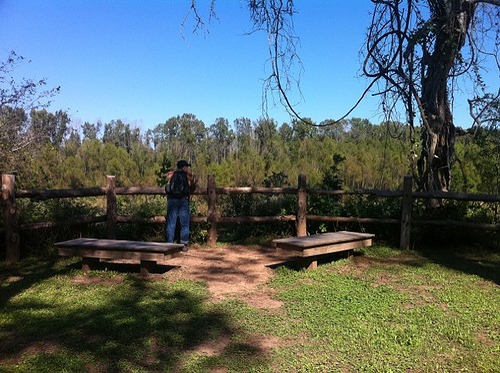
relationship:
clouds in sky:
[1, 90, 198, 145] [2, 2, 499, 132]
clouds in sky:
[73, 95, 123, 110] [2, 2, 499, 132]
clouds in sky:
[1, 0, 500, 122] [2, 2, 499, 132]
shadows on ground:
[4, 248, 269, 369] [205, 252, 395, 337]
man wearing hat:
[163, 157, 196, 251] [175, 158, 193, 170]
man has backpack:
[163, 157, 196, 251] [162, 168, 192, 198]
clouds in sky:
[1, 0, 500, 122] [110, 35, 202, 90]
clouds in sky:
[1, 0, 500, 122] [0, 1, 499, 146]